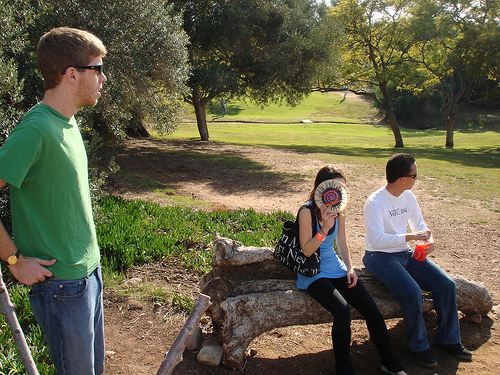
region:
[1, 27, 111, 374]
man in green shirt is standing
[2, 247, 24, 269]
man wearing a watch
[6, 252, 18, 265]
gold watch face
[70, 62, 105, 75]
man wearing black sunglasses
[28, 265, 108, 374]
man wearing blue jeans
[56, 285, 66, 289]
metal rivets on jeans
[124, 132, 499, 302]
a gravel path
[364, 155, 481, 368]
man sitting on a log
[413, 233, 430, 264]
a red label on a plastic bottle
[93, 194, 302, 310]
green grass next to path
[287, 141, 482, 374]
People sit on a log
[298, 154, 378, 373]
She covers her face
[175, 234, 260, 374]
The stump of a tree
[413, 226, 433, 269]
A red gatorade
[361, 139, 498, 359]
The man holds a bottle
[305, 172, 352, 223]
A white frisbee with swirls on it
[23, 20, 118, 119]
The man wears sun glasses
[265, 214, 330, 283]
The purse is black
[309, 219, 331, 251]
She has two braclets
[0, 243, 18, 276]
A wrist watch on the man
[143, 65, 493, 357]
people sitting on a log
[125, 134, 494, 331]
a man and woman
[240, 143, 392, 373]
a woman holding his face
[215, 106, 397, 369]
a woman hiding her face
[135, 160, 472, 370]
a large tree log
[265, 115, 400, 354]
a woman holding a black bag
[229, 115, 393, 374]
a woman wearing a shirt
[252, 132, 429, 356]
a woman wearing a blue shirt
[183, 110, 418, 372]
a woman wearing pants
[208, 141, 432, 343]
a woman wearing black pants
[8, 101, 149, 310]
man's shirt is green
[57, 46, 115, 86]
man is wearing sunglasses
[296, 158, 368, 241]
woman holding a frisbee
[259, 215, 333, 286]
woman carrying a bag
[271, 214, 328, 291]
the bag is black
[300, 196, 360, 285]
woman's shirt is blue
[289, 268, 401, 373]
woman's pants are black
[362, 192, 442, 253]
man's shirt is white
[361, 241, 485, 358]
man wearing blue jeans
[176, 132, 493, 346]
man and woman sitting on tree log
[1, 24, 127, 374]
Man is wearing sunglasses.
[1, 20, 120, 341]
The sunglasses are dark.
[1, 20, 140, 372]
The man has hair.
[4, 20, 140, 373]
Man's hair is short.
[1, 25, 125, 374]
Man's hair is brown.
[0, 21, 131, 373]
Man's hair is neat.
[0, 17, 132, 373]
Man's hair is tidy.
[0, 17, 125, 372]
The man is standing.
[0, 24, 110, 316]
Man is wearing watch.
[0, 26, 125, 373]
Watch has dark band.